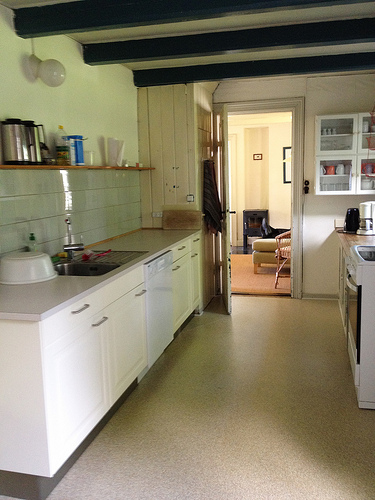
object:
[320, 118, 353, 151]
glass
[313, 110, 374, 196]
cabinet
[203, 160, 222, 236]
towel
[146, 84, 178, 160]
wall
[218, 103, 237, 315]
door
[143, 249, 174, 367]
dishwasher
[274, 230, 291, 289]
chair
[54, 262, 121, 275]
sink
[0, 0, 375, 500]
kitchen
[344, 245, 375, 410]
stove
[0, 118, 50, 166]
coffee pot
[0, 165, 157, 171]
brown shelf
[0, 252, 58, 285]
bowl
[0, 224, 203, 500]
cabinetry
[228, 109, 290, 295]
living room